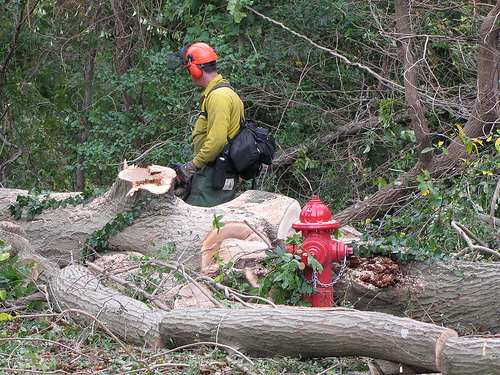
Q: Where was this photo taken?
A: In the woods.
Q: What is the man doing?
A: Cutting down trees.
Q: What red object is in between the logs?
A: A fire hydrant.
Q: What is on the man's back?
A: A bag.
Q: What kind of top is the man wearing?
A: A yellow jacket.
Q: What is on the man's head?
A: Helmet.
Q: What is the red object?
A: Hydrant.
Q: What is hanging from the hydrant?
A: Chain.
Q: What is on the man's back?
A: Backpack.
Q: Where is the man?
A: Woods.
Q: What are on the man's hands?
A: Gloves.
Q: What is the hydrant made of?
A: Metal.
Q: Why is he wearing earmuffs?
A: To protect his hearing.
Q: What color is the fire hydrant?
A: Red.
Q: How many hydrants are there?
A: 1.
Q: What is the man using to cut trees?
A: Chainsaw.